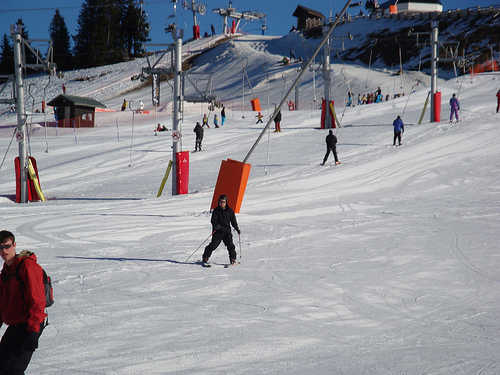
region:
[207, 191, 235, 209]
person has black cap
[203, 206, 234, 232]
person has black coat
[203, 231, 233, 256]
person has black pants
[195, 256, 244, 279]
person has skis turned inward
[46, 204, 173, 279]
tracks on white snow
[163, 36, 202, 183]
metal pole behind man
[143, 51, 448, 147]
many people on slopes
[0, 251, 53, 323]
boy has red jacket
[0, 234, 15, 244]
boy is wearing glasses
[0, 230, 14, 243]
boy has brown hair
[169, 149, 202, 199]
box is red in color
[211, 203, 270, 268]
man is in black outfit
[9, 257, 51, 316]
man in a red jacket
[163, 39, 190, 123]
the post is metallic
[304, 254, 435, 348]
floor is grey in color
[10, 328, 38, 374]
pants are black in color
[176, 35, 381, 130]
many people are i the field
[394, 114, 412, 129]
jacket is blue in color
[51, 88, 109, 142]
a hut in the middle of the field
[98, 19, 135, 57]
trees atre far beside the view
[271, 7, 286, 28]
this is the sky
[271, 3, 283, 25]
the sky is blue in color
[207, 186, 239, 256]
this is a man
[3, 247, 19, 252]
the man is light skinned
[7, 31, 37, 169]
this is a pole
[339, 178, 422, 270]
this is the snow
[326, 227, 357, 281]
the snow is white in color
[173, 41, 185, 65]
the pole is white in color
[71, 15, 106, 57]
this is a tree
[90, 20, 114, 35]
the leaves are green in color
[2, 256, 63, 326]
the jacket is red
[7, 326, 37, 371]
the pants are black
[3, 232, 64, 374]
the man has glasses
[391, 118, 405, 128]
the jacket is blue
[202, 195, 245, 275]
the man has goggles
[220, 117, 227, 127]
the pants are blue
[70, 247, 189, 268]
shadow is on the ground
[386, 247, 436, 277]
skitrail is on the snow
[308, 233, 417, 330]
the snow is white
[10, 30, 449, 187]
the poles are four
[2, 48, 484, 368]
lots of people at a ski resort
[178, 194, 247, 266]
a little kid on skis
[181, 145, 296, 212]
orange barrier around pole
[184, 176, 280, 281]
a kid in all black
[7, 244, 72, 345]
a red jacket and backpack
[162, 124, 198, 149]
a red and white sign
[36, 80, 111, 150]
a small brown building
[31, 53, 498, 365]
snow covers the ground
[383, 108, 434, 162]
a person in blue and black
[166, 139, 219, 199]
a red pad on pole